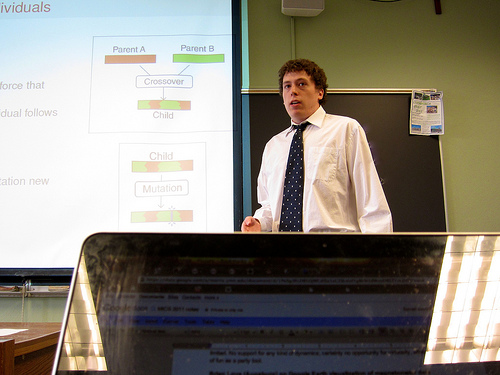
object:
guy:
[240, 61, 393, 235]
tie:
[277, 123, 308, 232]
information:
[0, 0, 241, 267]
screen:
[55, 231, 440, 374]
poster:
[408, 90, 445, 137]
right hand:
[241, 215, 262, 232]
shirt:
[252, 105, 393, 233]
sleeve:
[343, 120, 392, 234]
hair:
[277, 58, 327, 104]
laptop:
[51, 230, 500, 375]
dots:
[291, 185, 294, 188]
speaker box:
[280, 0, 325, 17]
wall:
[243, 7, 499, 232]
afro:
[278, 58, 328, 107]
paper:
[409, 90, 446, 136]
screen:
[0, 1, 232, 270]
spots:
[296, 154, 300, 157]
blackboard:
[236, 88, 448, 233]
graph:
[90, 36, 232, 233]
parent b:
[181, 44, 215, 52]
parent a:
[112, 46, 146, 54]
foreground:
[53, 230, 446, 375]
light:
[422, 234, 498, 368]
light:
[53, 259, 104, 375]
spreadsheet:
[0, 0, 232, 272]